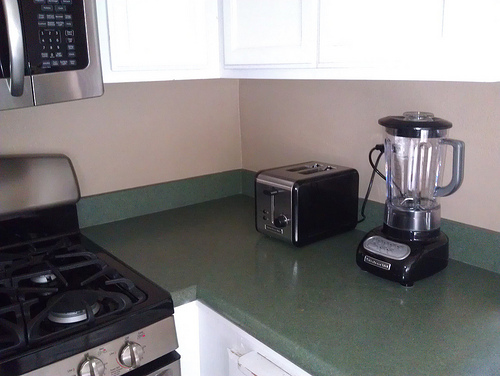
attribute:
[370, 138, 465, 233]
blender — glass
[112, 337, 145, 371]
dial — shiny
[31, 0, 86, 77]
control panel — microwave oven control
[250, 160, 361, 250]
toaster — black, stainless, steel, chrome metal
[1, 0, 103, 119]
microwave — over-the-stove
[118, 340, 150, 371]
metal dial — shiny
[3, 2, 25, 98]
microwave handle — grey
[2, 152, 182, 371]
oven — grey metal , black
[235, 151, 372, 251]
toaster — silver, black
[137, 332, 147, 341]
light — LED, red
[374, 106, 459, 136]
cap — round, plastic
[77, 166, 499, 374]
kitchen counter — green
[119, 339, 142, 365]
handle — gray, metal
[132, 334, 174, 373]
trim — chrome 